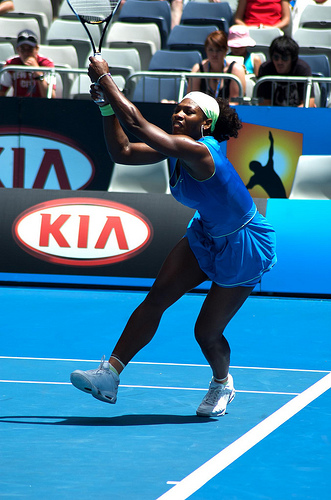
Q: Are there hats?
A: Yes, there is a hat.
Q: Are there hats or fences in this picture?
A: Yes, there is a hat.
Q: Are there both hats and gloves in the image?
A: No, there is a hat but no gloves.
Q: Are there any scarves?
A: No, there are no scarves.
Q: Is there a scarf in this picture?
A: No, there are no scarves.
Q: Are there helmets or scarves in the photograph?
A: No, there are no scarves or helmets.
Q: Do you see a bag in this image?
A: No, there are no bags.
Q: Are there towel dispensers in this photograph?
A: No, there are no towel dispensers.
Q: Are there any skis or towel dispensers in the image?
A: No, there are no towel dispensers or skis.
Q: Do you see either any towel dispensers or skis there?
A: No, there are no towel dispensers or skis.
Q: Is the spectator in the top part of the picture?
A: Yes, the spectator is in the top of the image.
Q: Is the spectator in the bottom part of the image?
A: No, the spectator is in the top of the image.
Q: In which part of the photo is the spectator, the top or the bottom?
A: The spectator is in the top of the image.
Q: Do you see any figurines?
A: No, there are no figurines.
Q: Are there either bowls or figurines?
A: No, there are no figurines or bowls.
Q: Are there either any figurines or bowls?
A: No, there are no figurines or bowls.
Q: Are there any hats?
A: Yes, there is a hat.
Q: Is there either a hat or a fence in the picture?
A: Yes, there is a hat.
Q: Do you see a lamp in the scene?
A: No, there are no lamps.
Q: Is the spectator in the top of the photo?
A: Yes, the spectator is in the top of the image.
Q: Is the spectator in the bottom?
A: No, the spectator is in the top of the image.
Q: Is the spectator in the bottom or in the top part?
A: The spectator is in the top of the image.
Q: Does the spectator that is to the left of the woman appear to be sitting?
A: Yes, the spectator is sitting.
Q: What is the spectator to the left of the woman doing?
A: The spectator is sitting.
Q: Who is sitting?
A: The spectator is sitting.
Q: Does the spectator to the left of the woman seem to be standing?
A: No, the spectator is sitting.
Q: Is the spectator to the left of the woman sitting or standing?
A: The spectator is sitting.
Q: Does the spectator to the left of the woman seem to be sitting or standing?
A: The spectator is sitting.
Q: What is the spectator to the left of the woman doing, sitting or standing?
A: The spectator is sitting.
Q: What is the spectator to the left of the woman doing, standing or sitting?
A: The spectator is sitting.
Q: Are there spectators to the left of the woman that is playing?
A: Yes, there is a spectator to the left of the woman.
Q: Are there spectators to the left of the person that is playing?
A: Yes, there is a spectator to the left of the woman.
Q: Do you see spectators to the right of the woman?
A: No, the spectator is to the left of the woman.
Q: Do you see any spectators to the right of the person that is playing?
A: No, the spectator is to the left of the woman.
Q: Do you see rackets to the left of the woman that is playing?
A: No, there is a spectator to the left of the woman.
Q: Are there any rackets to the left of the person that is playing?
A: No, there is a spectator to the left of the woman.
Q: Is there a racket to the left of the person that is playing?
A: No, there is a spectator to the left of the woman.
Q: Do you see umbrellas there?
A: No, there are no umbrellas.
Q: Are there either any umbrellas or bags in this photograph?
A: No, there are no umbrellas or bags.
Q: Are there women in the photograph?
A: Yes, there is a woman.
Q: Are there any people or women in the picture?
A: Yes, there is a woman.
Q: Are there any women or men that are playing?
A: Yes, the woman is playing.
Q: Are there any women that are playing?
A: Yes, there is a woman that is playing.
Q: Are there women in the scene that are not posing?
A: Yes, there is a woman that is playing.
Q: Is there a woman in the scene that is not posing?
A: Yes, there is a woman that is playing.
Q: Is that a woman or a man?
A: That is a woman.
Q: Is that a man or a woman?
A: That is a woman.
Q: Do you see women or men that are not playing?
A: No, there is a woman but she is playing.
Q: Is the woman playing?
A: Yes, the woman is playing.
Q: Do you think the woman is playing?
A: Yes, the woman is playing.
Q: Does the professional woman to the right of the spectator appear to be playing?
A: Yes, the woman is playing.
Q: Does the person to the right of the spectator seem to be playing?
A: Yes, the woman is playing.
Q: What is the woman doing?
A: The woman is playing.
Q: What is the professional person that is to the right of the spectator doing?
A: The woman is playing.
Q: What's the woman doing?
A: The woman is playing.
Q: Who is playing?
A: The woman is playing.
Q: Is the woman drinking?
A: No, the woman is playing.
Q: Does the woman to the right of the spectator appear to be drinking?
A: No, the woman is playing.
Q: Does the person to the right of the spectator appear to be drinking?
A: No, the woman is playing.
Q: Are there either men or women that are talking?
A: No, there is a woman but she is playing.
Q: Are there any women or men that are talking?
A: No, there is a woman but she is playing.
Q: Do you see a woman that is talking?
A: No, there is a woman but she is playing.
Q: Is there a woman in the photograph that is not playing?
A: No, there is a woman but she is playing.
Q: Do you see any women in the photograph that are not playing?
A: No, there is a woman but she is playing.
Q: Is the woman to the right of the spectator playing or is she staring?
A: The woman is playing.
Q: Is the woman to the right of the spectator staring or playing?
A: The woman is playing.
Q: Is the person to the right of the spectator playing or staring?
A: The woman is playing.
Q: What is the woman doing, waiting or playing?
A: The woman is playing.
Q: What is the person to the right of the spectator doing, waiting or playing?
A: The woman is playing.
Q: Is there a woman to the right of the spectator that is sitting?
A: Yes, there is a woman to the right of the spectator.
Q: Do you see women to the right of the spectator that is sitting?
A: Yes, there is a woman to the right of the spectator.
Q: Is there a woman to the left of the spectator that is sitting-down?
A: No, the woman is to the right of the spectator.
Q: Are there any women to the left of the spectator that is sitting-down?
A: No, the woman is to the right of the spectator.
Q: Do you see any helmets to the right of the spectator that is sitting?
A: No, there is a woman to the right of the spectator.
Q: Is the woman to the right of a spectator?
A: Yes, the woman is to the right of a spectator.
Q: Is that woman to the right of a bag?
A: No, the woman is to the right of a spectator.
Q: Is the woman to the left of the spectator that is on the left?
A: No, the woman is to the right of the spectator.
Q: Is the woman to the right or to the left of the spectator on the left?
A: The woman is to the right of the spectator.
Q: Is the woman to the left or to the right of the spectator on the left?
A: The woman is to the right of the spectator.